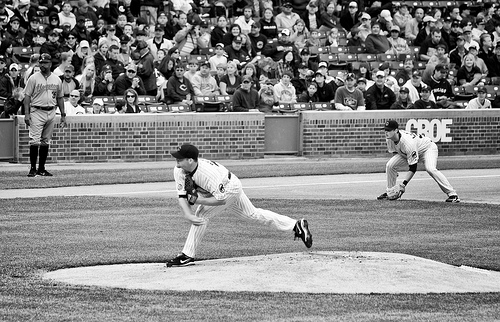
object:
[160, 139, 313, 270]
pitcher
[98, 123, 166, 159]
wall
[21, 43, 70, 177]
coach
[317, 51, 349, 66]
seats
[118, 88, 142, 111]
woman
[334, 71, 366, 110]
man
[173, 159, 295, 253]
suit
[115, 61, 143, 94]
audience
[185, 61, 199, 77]
children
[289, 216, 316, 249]
shoes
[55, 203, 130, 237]
grass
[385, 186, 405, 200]
mitt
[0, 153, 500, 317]
field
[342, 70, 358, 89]
head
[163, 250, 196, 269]
shoe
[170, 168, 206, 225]
arm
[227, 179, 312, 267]
leg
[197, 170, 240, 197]
belt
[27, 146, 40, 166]
sock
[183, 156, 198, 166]
ear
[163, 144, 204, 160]
cap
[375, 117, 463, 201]
baseman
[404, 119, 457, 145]
croe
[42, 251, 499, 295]
pitcher mount